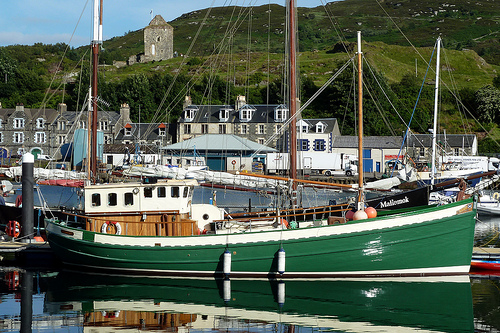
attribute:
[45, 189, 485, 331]
boat — green, white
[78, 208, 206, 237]
housing — wooden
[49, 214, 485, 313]
boat — one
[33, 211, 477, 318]
boat — one, green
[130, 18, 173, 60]
castle — one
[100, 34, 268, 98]
hill — one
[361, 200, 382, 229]
ball — orange 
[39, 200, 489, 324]
boat — white, green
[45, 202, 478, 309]
boat — green 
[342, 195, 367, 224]
ball — white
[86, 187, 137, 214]
windows — some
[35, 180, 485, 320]
boat — green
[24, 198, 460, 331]
boat — green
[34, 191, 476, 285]
boat — green, white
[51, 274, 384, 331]
water — clear, smooth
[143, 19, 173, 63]
buildings — large, stone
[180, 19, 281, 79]
hill — green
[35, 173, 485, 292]
boat — fishing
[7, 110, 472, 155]
building — old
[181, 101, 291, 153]
building — old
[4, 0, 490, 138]
mountain background — scenic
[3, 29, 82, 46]
clouds — white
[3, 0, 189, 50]
sky — blue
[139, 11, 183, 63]
structure — gray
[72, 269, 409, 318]
reflection — boat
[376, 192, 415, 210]
lettering — white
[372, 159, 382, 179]
door — blue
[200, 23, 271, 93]
grass — green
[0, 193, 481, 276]
boat — green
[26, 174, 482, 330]
boat — green, white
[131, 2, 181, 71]
tower — in the background